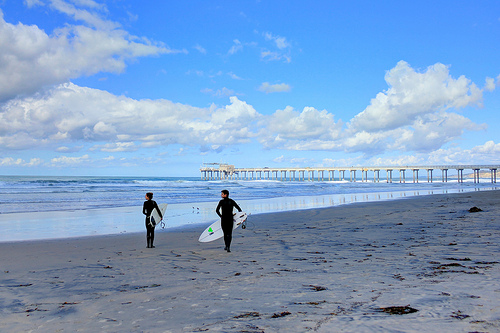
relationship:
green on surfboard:
[206, 226, 216, 233] [197, 205, 248, 245]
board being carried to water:
[198, 212, 247, 243] [6, 170, 356, 209]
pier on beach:
[193, 157, 498, 187] [2, 185, 484, 332]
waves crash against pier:
[247, 170, 284, 185] [193, 147, 498, 184]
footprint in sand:
[232, 270, 242, 280] [32, 255, 195, 325]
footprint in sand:
[170, 262, 183, 269] [32, 255, 195, 325]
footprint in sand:
[270, 306, 291, 319] [32, 255, 195, 325]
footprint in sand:
[235, 310, 255, 317] [32, 255, 195, 325]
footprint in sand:
[294, 253, 306, 265] [32, 255, 195, 325]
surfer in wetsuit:
[142, 192, 163, 248] [142, 200, 157, 245]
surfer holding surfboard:
[142, 192, 163, 248] [178, 199, 279, 241]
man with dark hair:
[215, 189, 244, 253] [218, 189, 232, 194]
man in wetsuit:
[215, 189, 244, 253] [216, 202, 237, 246]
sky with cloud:
[0, 2, 498, 183] [2, 58, 477, 151]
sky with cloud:
[0, 2, 498, 183] [1, 7, 180, 101]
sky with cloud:
[0, 2, 498, 183] [310, 136, 499, 188]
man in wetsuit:
[215, 189, 244, 253] [215, 197, 242, 252]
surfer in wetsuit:
[142, 192, 163, 248] [141, 199, 161, 246]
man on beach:
[215, 189, 244, 253] [2, 185, 484, 332]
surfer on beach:
[142, 192, 163, 248] [2, 185, 484, 332]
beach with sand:
[2, 185, 484, 332] [0, 188, 498, 330]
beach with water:
[2, 185, 484, 332] [4, 178, 496, 255]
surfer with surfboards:
[142, 192, 163, 248] [150, 188, 172, 248]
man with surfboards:
[215, 189, 244, 253] [198, 206, 220, 253]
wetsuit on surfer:
[218, 198, 242, 250] [214, 184, 241, 257]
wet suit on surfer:
[139, 199, 166, 249] [137, 186, 167, 251]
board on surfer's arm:
[148, 202, 168, 224] [153, 202, 163, 219]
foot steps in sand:
[133, 234, 303, 286] [0, 188, 498, 330]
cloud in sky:
[206, 74, 288, 168] [185, 37, 286, 89]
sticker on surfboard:
[207, 223, 212, 238] [194, 212, 251, 242]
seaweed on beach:
[379, 305, 417, 314] [2, 185, 484, 332]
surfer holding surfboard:
[142, 192, 163, 248] [197, 222, 224, 259]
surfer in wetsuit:
[142, 192, 163, 248] [140, 199, 160, 251]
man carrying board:
[215, 189, 244, 253] [193, 212, 263, 244]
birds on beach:
[185, 201, 206, 213] [0, 186, 498, 276]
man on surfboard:
[215, 189, 244, 253] [200, 210, 248, 241]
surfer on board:
[140, 191, 160, 247] [149, 202, 168, 227]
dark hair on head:
[221, 189, 230, 197] [209, 190, 237, 205]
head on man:
[209, 190, 237, 205] [214, 189, 243, 252]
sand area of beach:
[316, 217, 387, 322] [2, 185, 484, 332]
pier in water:
[198, 164, 500, 187] [1, 173, 498, 240]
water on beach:
[10, 168, 289, 213] [2, 185, 484, 332]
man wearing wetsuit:
[215, 186, 247, 253] [214, 197, 246, 257]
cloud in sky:
[339, 58, 479, 158] [0, 2, 498, 183]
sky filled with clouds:
[0, 2, 498, 183] [346, 57, 493, 139]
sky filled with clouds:
[0, 2, 498, 183] [6, 81, 251, 154]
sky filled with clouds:
[0, 2, 498, 183] [3, 1, 187, 94]